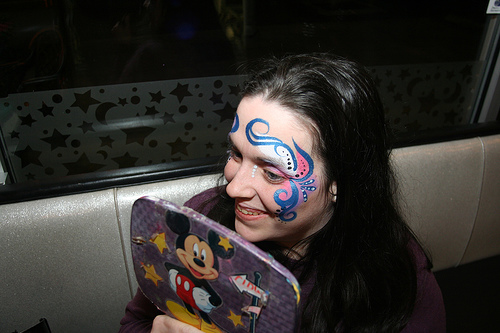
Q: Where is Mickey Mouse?
A: On the back of the mirror.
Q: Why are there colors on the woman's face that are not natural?
A: Her face is painted.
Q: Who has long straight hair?
A: The woman.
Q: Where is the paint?
A: On the woman's face.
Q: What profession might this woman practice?
A: Clown.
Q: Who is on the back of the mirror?
A: Mickey Mouse.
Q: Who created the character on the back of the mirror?
A: Walt Disney.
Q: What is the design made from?
A: Paint.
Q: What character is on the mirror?
A: Mickey Mouse.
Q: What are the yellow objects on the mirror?
A: Stars.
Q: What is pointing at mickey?
A: Arrows.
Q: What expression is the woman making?
A: Happy.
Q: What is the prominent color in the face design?
A: Blue.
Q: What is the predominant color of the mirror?
A: Purple.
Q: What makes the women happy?
A: Face Design.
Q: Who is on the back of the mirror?
A: Mickey Mouse.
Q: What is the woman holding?
A: Mirror.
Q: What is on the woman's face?
A: Face paint.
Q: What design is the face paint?
A: Pink, white, blue swirls.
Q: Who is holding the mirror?
A: Woman with face paint.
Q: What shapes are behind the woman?
A: Stars and moons.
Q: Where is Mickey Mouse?
A: On back of the mirror.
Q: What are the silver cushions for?
A: Back support.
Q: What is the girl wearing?
A: Purple shirt.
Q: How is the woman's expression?
A: Happy.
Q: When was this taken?
A: Nighttime.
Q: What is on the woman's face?
A: Paint.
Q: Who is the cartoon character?
A: Mickey Mouse.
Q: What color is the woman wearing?
A: Black.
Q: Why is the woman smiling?
A: She is happy.